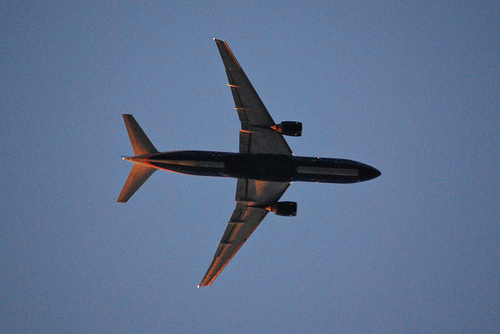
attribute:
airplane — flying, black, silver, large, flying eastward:
[115, 36, 382, 290]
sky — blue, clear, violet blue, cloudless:
[3, 2, 497, 334]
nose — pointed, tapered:
[356, 159, 383, 187]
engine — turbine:
[272, 119, 303, 138]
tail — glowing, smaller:
[117, 112, 165, 206]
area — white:
[296, 166, 360, 179]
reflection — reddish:
[126, 128, 154, 188]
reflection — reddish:
[200, 238, 244, 289]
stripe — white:
[138, 158, 227, 169]